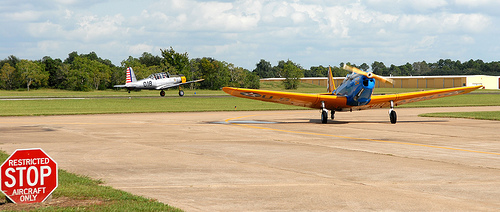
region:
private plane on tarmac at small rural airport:
[0, 3, 497, 208]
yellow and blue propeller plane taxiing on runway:
[222, 64, 485, 123]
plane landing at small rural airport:
[116, 65, 202, 97]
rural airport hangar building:
[256, 73, 498, 93]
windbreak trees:
[2, 50, 498, 92]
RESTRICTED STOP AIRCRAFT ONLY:
[0, 146, 59, 206]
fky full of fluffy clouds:
[0, 70, 497, 148]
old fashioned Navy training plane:
[116, 65, 204, 96]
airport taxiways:
[0, 103, 499, 210]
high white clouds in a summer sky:
[0, 1, 499, 117]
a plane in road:
[88, 43, 205, 109]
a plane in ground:
[240, 49, 415, 132]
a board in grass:
[1, 125, 56, 210]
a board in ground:
[0, 134, 64, 197]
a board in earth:
[9, 138, 83, 208]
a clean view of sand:
[117, 83, 304, 203]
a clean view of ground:
[109, 103, 286, 196]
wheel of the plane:
[304, 90, 415, 120]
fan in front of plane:
[325, 53, 422, 108]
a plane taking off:
[222, 65, 483, 121]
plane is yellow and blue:
[222, 66, 479, 123]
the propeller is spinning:
[340, 64, 392, 84]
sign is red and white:
[2, 149, 56, 201]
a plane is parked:
[115, 67, 204, 97]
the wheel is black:
[320, 109, 327, 119]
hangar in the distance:
[260, 73, 499, 87]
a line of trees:
[0, 46, 499, 88]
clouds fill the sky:
[0, 3, 499, 53]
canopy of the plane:
[156, 72, 168, 79]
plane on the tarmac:
[210, 54, 482, 128]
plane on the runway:
[105, 58, 216, 105]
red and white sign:
[1, 140, 61, 205]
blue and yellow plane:
[211, 53, 496, 124]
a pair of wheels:
[155, 85, 190, 98]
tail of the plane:
[116, 58, 138, 97]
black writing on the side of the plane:
[139, 79, 155, 87]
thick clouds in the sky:
[0, 0, 485, 67]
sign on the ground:
[0, 145, 70, 204]